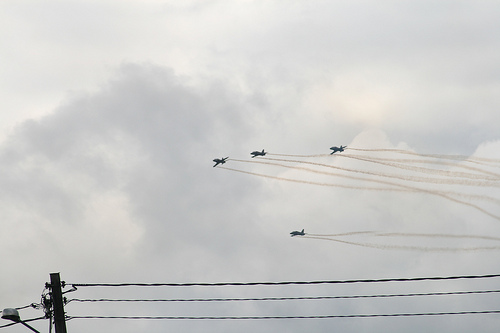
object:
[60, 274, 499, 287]
line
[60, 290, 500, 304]
line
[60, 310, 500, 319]
line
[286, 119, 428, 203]
person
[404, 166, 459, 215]
ground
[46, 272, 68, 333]
pole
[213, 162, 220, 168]
wing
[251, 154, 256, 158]
wing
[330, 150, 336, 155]
wing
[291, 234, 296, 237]
wing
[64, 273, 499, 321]
power lines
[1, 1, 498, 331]
sky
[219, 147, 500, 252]
smoke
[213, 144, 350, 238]
jets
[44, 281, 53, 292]
knob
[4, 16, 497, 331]
cloud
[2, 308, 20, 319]
bulb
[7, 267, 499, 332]
electrical line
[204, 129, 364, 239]
formation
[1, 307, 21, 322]
street lamp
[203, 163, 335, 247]
formation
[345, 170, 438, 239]
formation